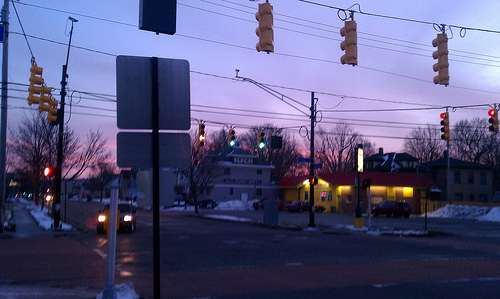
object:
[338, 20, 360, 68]
street lights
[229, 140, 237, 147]
lights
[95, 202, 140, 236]
car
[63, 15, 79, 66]
traffic camera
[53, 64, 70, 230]
pole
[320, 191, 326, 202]
sign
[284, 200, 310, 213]
cars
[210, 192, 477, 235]
parking lot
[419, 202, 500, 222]
snow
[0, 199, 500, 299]
ground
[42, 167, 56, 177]
hand signal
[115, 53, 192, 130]
back of street sign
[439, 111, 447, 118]
street lights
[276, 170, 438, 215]
building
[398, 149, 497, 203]
victorian house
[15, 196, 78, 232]
snow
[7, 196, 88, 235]
sidewalk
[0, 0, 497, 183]
sky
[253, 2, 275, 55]
street light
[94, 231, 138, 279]
reflection of lights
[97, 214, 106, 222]
car headlights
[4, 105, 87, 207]
trees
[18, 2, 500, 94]
wires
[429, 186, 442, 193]
street sign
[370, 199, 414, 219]
car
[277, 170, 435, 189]
top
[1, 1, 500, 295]
scene